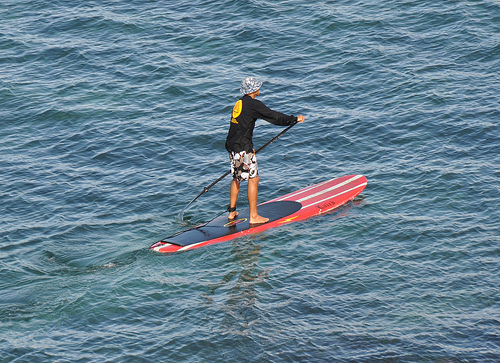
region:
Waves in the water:
[1, 0, 497, 360]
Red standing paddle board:
[148, 168, 368, 256]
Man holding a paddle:
[171, 77, 305, 227]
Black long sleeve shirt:
[221, 93, 296, 153]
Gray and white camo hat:
[234, 77, 266, 92]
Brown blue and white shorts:
[226, 145, 259, 179]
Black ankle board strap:
[185, 203, 235, 227]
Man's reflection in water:
[203, 225, 283, 353]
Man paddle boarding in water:
[147, 73, 367, 258]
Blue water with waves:
[0, 0, 499, 362]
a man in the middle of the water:
[95, 46, 387, 283]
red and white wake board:
[156, 180, 371, 263]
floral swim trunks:
[226, 149, 282, 190]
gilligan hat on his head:
[242, 75, 258, 95]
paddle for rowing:
[175, 170, 225, 220]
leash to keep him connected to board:
[191, 210, 239, 228]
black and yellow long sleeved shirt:
[225, 98, 288, 152]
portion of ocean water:
[354, 196, 422, 359]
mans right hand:
[292, 113, 306, 123]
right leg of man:
[247, 178, 264, 230]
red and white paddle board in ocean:
[314, 176, 362, 203]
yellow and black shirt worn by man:
[229, 98, 252, 147]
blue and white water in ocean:
[21, 16, 70, 61]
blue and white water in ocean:
[28, 136, 68, 177]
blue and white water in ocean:
[44, 302, 114, 329]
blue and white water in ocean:
[178, 298, 269, 351]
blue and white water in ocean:
[322, 289, 361, 328]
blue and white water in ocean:
[368, 274, 443, 334]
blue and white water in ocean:
[379, 217, 416, 264]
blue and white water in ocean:
[397, 105, 423, 154]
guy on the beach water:
[110, 56, 410, 285]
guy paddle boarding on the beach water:
[133, 66, 382, 278]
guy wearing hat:
[211, 71, 298, 230]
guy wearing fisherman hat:
[216, 63, 304, 238]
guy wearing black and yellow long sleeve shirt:
[206, 65, 311, 237]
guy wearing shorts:
[209, 73, 310, 240]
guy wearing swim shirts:
[211, 74, 308, 231]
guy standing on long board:
[138, 64, 377, 274]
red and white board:
[142, 163, 376, 265]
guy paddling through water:
[126, 71, 396, 271]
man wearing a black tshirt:
[217, 64, 292, 228]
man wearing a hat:
[237, 52, 269, 227]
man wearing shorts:
[202, 65, 275, 229]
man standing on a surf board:
[205, 65, 275, 239]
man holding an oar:
[168, 55, 318, 220]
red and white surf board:
[92, 195, 369, 253]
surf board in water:
[151, 179, 384, 259]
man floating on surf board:
[145, 55, 330, 281]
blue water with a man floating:
[363, 232, 466, 333]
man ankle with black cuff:
[215, 192, 244, 230]